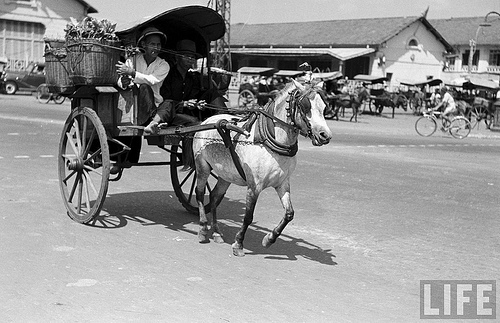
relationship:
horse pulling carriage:
[177, 77, 330, 250] [56, 0, 229, 224]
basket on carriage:
[35, 24, 126, 86] [56, 0, 229, 224]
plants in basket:
[64, 17, 123, 42] [35, 24, 126, 86]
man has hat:
[113, 21, 178, 141] [141, 23, 169, 43]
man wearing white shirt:
[113, 21, 178, 141] [123, 51, 167, 97]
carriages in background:
[0, 1, 500, 130] [14, 5, 495, 145]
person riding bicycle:
[414, 82, 474, 141] [413, 107, 474, 137]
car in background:
[4, 53, 46, 94] [14, 5, 495, 145]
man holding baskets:
[113, 21, 178, 141] [35, 24, 126, 86]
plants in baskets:
[64, 17, 123, 42] [35, 24, 126, 86]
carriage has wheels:
[56, 0, 229, 224] [61, 111, 227, 227]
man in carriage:
[113, 21, 178, 137] [56, 0, 229, 224]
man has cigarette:
[113, 21, 178, 141] [148, 51, 156, 59]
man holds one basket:
[113, 21, 178, 141] [35, 24, 126, 86]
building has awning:
[208, 21, 451, 89] [213, 46, 369, 68]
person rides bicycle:
[414, 82, 474, 141] [413, 107, 474, 137]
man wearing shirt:
[167, 43, 229, 115] [168, 68, 209, 98]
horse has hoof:
[177, 77, 330, 250] [254, 229, 279, 251]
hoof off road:
[254, 229, 279, 251] [7, 94, 497, 321]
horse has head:
[177, 77, 330, 250] [284, 77, 334, 142]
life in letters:
[416, 272, 500, 322] [421, 285, 492, 319]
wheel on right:
[166, 114, 235, 214] [165, 21, 338, 226]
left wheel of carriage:
[59, 112, 110, 221] [56, 0, 229, 224]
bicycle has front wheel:
[413, 107, 474, 137] [415, 114, 438, 133]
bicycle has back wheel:
[413, 107, 474, 137] [449, 115, 472, 135]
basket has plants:
[35, 24, 126, 86] [64, 17, 123, 42]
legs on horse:
[196, 166, 295, 258] [177, 77, 330, 250]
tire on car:
[8, 81, 19, 93] [4, 53, 46, 94]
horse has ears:
[177, 77, 330, 250] [290, 72, 332, 97]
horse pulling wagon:
[177, 77, 330, 250] [56, 0, 229, 224]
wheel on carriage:
[166, 114, 235, 214] [56, 0, 229, 224]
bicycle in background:
[413, 107, 474, 137] [14, 5, 495, 145]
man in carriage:
[113, 21, 178, 141] [56, 0, 229, 224]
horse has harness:
[177, 77, 330, 250] [175, 92, 299, 151]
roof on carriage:
[111, 5, 232, 36] [56, 0, 229, 224]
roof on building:
[226, 16, 447, 58] [208, 21, 451, 89]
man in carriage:
[167, 43, 229, 115] [56, 0, 229, 224]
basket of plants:
[35, 24, 126, 86] [64, 17, 123, 42]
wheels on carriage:
[61, 111, 227, 227] [56, 0, 229, 224]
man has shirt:
[167, 43, 229, 115] [168, 68, 209, 98]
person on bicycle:
[414, 82, 474, 141] [413, 107, 474, 137]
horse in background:
[329, 89, 367, 118] [14, 5, 495, 145]